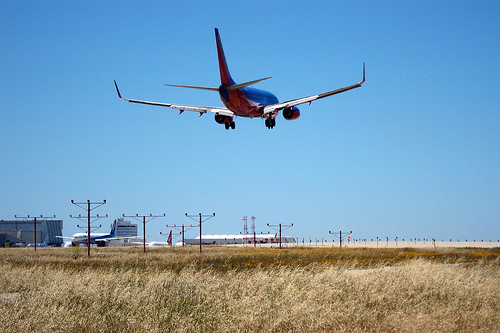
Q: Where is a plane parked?
A: Airport.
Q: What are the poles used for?
A: Lights.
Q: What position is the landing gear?
A: Down.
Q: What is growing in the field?
A: Grass.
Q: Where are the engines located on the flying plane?
A: Below the wings.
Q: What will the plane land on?
A: Runway.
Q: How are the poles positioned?
A: In rows.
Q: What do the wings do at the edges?
A: Curve up.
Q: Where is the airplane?
A: In air.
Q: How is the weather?
A: Clear.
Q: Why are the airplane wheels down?
A: For landing.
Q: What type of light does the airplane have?
A: Daylight.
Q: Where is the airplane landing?
A: Airport runway.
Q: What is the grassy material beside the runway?
A: Dying grass.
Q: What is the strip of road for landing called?
A: Runway.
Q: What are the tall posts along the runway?
A: Light posts.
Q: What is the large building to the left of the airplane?
A: Airport.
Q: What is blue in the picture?
A: The sky.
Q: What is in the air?
A: A plane.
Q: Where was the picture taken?
A: At an airport.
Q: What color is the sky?
A: Blue.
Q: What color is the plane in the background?
A: White.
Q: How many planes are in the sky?
A: One.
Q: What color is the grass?
A: Brown.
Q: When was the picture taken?
A: During the day.